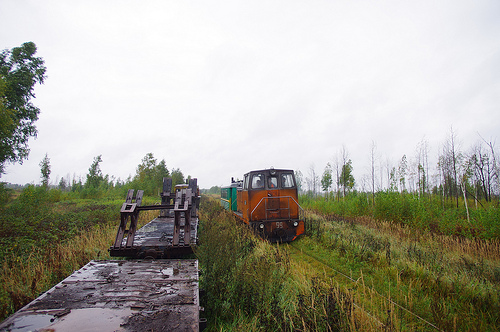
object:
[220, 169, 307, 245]
train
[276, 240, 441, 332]
tracks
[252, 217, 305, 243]
train engine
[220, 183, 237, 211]
train cars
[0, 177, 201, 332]
flatbed rail car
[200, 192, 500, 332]
grass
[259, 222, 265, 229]
headlights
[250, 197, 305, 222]
railing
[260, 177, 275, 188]
engineer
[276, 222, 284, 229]
95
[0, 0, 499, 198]
sky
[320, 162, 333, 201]
trees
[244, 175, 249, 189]
windows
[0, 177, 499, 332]
field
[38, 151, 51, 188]
trees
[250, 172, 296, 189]
windshield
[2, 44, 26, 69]
leaves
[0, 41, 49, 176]
tree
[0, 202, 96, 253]
weeds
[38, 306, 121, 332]
puddle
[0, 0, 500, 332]
section